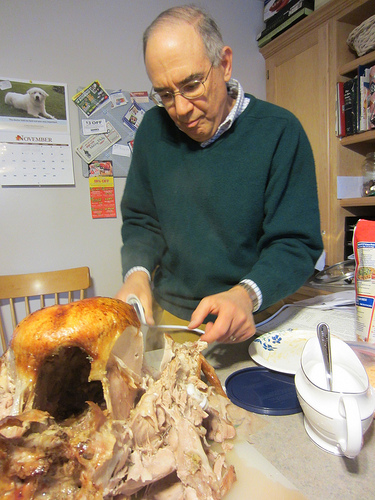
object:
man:
[113, 4, 323, 344]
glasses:
[147, 61, 217, 108]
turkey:
[0, 296, 247, 500]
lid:
[224, 366, 302, 417]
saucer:
[247, 327, 316, 376]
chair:
[0, 266, 93, 352]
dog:
[4, 86, 57, 120]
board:
[75, 86, 156, 178]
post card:
[70, 80, 112, 119]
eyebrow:
[153, 86, 170, 92]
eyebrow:
[178, 71, 207, 85]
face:
[152, 59, 228, 144]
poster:
[0, 77, 75, 188]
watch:
[237, 281, 259, 312]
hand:
[187, 284, 256, 345]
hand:
[114, 270, 155, 326]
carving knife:
[127, 293, 148, 325]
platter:
[0, 296, 232, 500]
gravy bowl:
[294, 333, 375, 461]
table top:
[249, 457, 375, 500]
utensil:
[316, 321, 333, 391]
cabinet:
[254, 0, 373, 276]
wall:
[2, 0, 259, 252]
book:
[336, 81, 346, 136]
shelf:
[339, 126, 375, 147]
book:
[343, 79, 355, 136]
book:
[357, 64, 371, 134]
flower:
[262, 342, 273, 351]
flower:
[272, 334, 282, 344]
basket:
[345, 12, 374, 58]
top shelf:
[337, 49, 375, 75]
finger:
[221, 322, 249, 343]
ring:
[230, 335, 236, 342]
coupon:
[81, 118, 108, 136]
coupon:
[88, 160, 117, 219]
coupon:
[74, 120, 121, 165]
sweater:
[119, 92, 325, 324]